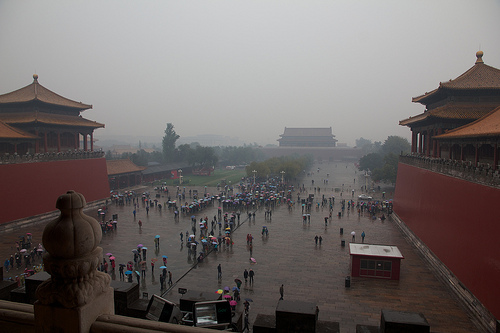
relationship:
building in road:
[348, 243, 405, 280] [49, 159, 489, 331]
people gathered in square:
[93, 173, 405, 308] [1, 159, 496, 329]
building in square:
[347, 242, 404, 279] [3, 185, 495, 330]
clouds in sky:
[6, 0, 498, 146] [0, 4, 493, 154]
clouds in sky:
[61, 22, 377, 109] [0, 4, 493, 154]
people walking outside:
[0, 159, 393, 333] [0, 3, 492, 330]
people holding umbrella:
[0, 159, 393, 333] [145, 236, 163, 247]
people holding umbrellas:
[0, 159, 393, 333] [247, 252, 261, 268]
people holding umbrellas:
[0, 159, 393, 333] [159, 246, 171, 261]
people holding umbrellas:
[0, 159, 393, 333] [150, 232, 167, 242]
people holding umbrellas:
[0, 159, 393, 333] [348, 228, 360, 237]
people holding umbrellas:
[0, 159, 393, 333] [107, 252, 116, 261]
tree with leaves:
[159, 120, 181, 157] [354, 131, 406, 178]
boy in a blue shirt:
[152, 232, 163, 252] [154, 241, 161, 248]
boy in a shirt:
[119, 265, 138, 279] [121, 263, 131, 279]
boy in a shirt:
[278, 284, 285, 299] [281, 282, 288, 302]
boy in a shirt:
[128, 171, 168, 201] [142, 185, 153, 196]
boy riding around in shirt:
[271, 277, 288, 306] [270, 280, 289, 296]